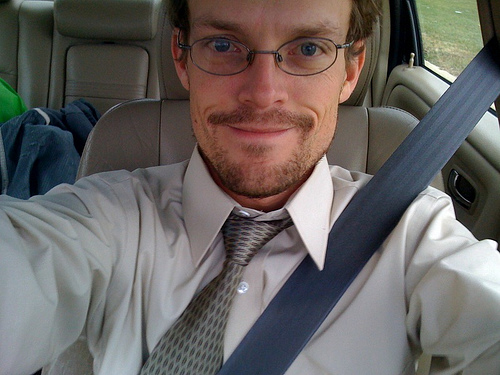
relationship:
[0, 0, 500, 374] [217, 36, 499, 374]
man wearing seatbelt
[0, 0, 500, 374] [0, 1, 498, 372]
man inside car